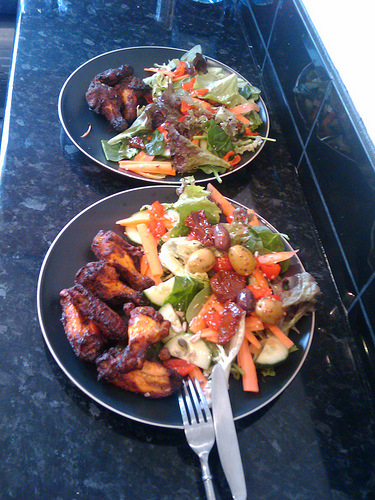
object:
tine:
[192, 376, 212, 421]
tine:
[186, 376, 204, 422]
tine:
[183, 383, 199, 423]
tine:
[174, 383, 188, 426]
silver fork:
[173, 377, 216, 500]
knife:
[208, 362, 247, 499]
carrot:
[207, 181, 239, 223]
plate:
[56, 45, 269, 188]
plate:
[37, 183, 314, 431]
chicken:
[114, 304, 172, 373]